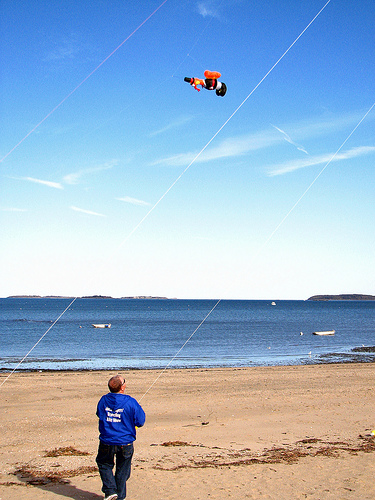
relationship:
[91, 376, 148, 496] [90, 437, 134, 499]
man wearing jeans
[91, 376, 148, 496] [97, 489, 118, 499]
man wearing shoes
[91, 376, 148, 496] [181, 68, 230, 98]
man flying kite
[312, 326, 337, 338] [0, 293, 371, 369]
boat riding on water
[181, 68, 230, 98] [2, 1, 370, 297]
kite flying in sky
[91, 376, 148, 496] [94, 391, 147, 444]
man wearing shirt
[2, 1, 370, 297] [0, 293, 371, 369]
sky above water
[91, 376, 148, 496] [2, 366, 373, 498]
man standing at beach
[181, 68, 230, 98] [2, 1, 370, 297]
kite floating in sky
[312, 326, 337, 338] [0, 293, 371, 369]
boat sitting in water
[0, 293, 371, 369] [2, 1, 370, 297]
water under sky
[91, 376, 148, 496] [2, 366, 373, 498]
man standing at a beach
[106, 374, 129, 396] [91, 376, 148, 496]
head of a man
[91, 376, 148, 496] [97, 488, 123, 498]
man wearing shoes